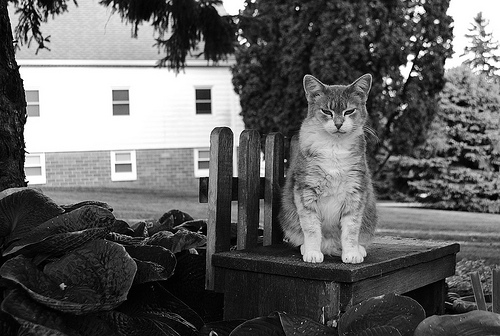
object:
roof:
[2, 0, 251, 67]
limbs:
[292, 198, 367, 264]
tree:
[0, 0, 240, 192]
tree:
[380, 64, 500, 214]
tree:
[457, 11, 499, 77]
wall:
[20, 66, 268, 193]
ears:
[345, 72, 373, 94]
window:
[111, 89, 130, 116]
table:
[210, 233, 461, 331]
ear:
[302, 73, 324, 95]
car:
[276, 72, 381, 263]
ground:
[22, 183, 499, 267]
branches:
[7, 0, 79, 56]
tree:
[228, 0, 456, 180]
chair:
[204, 126, 460, 327]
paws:
[300, 251, 324, 263]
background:
[0, 0, 499, 221]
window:
[23, 90, 41, 118]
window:
[193, 87, 212, 114]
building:
[6, 0, 267, 202]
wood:
[210, 252, 340, 326]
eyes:
[343, 108, 357, 116]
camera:
[1, 49, 457, 265]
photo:
[0, 0, 499, 335]